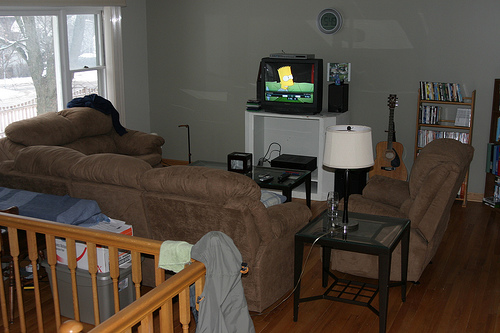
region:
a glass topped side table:
[292, 197, 428, 317]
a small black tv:
[235, 37, 348, 117]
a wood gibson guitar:
[361, 84, 421, 195]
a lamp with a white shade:
[313, 113, 384, 251]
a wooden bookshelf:
[406, 68, 485, 221]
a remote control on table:
[256, 161, 305, 188]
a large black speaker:
[320, 73, 360, 118]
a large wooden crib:
[0, 191, 277, 328]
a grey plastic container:
[28, 236, 156, 328]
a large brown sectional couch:
[9, 86, 328, 329]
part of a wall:
[384, 14, 444, 61]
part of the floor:
[432, 250, 479, 305]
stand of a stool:
[357, 278, 397, 324]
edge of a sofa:
[241, 249, 274, 300]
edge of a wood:
[150, 292, 184, 309]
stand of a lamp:
[331, 185, 357, 225]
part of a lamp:
[327, 147, 362, 174]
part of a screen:
[273, 70, 313, 102]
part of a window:
[78, 65, 105, 95]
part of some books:
[423, 80, 460, 96]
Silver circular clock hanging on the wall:
[313, 8, 350, 33]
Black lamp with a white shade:
[318, 120, 374, 233]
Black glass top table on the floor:
[282, 200, 408, 331]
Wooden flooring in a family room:
[424, 223, 497, 323]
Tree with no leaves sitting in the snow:
[12, 4, 84, 120]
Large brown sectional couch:
[0, 106, 317, 316]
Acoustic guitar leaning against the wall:
[363, 89, 406, 186]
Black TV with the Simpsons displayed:
[252, 54, 321, 113]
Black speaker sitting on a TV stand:
[324, 82, 351, 112]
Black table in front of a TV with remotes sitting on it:
[159, 151, 309, 206]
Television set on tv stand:
[247, 48, 346, 114]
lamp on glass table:
[321, 116, 377, 233]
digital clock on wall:
[312, 4, 354, 39]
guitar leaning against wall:
[366, 79, 421, 204]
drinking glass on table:
[320, 186, 345, 226]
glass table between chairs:
[284, 191, 415, 321]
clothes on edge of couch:
[55, 85, 151, 141]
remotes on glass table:
[257, 162, 304, 194]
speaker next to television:
[327, 73, 356, 120]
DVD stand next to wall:
[408, 72, 481, 236]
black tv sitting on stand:
[247, 37, 330, 129]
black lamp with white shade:
[308, 116, 412, 321]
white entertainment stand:
[231, 92, 354, 232]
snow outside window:
[3, 26, 110, 113]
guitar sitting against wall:
[362, 86, 430, 215]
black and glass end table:
[285, 197, 405, 325]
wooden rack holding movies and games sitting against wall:
[402, 66, 494, 231]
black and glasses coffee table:
[179, 143, 333, 238]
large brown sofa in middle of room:
[4, 72, 356, 309]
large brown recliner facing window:
[324, 123, 496, 319]